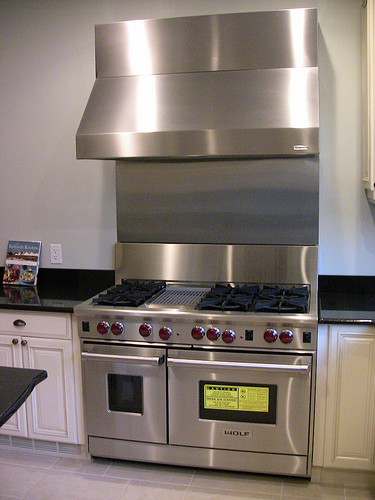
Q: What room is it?
A: It is a kitchen.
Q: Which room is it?
A: It is a kitchen.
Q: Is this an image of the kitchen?
A: Yes, it is showing the kitchen.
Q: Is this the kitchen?
A: Yes, it is the kitchen.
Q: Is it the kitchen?
A: Yes, it is the kitchen.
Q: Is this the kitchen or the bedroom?
A: It is the kitchen.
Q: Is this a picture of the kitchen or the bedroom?
A: It is showing the kitchen.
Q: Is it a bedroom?
A: No, it is a kitchen.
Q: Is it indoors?
A: Yes, it is indoors.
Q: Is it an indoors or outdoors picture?
A: It is indoors.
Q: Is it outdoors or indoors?
A: It is indoors.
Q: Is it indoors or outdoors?
A: It is indoors.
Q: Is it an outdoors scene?
A: No, it is indoors.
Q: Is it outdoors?
A: No, it is indoors.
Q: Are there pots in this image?
A: No, there are no pots.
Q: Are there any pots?
A: No, there are no pots.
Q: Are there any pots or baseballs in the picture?
A: No, there are no pots or baseballs.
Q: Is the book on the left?
A: Yes, the book is on the left of the image.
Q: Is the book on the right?
A: No, the book is on the left of the image.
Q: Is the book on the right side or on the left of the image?
A: The book is on the left of the image.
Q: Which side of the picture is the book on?
A: The book is on the left of the image.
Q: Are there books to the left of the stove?
A: Yes, there is a book to the left of the stove.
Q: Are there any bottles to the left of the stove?
A: No, there is a book to the left of the stove.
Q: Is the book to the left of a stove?
A: Yes, the book is to the left of a stove.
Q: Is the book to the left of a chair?
A: No, the book is to the left of a stove.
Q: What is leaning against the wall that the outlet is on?
A: The book is leaning against the wall.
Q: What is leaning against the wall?
A: The book is leaning against the wall.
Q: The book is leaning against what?
A: The book is leaning against the wall.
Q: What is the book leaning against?
A: The book is leaning against the wall.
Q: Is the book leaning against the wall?
A: Yes, the book is leaning against the wall.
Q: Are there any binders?
A: No, there are no binders.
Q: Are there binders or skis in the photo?
A: No, there are no binders or skis.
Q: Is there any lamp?
A: No, there are no lamps.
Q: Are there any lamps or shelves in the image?
A: No, there are no lamps or shelves.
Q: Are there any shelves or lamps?
A: No, there are no lamps or shelves.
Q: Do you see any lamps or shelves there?
A: No, there are no lamps or shelves.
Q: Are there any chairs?
A: No, there are no chairs.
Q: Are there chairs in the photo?
A: No, there are no chairs.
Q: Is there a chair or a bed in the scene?
A: No, there are no chairs or beds.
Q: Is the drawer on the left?
A: Yes, the drawer is on the left of the image.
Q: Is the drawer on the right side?
A: No, the drawer is on the left of the image.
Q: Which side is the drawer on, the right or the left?
A: The drawer is on the left of the image.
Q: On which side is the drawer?
A: The drawer is on the left of the image.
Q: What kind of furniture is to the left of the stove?
A: The piece of furniture is a drawer.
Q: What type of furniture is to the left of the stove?
A: The piece of furniture is a drawer.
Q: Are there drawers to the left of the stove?
A: Yes, there is a drawer to the left of the stove.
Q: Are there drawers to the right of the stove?
A: No, the drawer is to the left of the stove.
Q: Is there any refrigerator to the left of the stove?
A: No, there is a drawer to the left of the stove.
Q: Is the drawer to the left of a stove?
A: Yes, the drawer is to the left of a stove.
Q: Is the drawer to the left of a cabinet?
A: No, the drawer is to the left of a stove.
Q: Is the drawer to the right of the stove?
A: No, the drawer is to the left of the stove.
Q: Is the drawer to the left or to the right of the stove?
A: The drawer is to the left of the stove.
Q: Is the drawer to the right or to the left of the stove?
A: The drawer is to the left of the stove.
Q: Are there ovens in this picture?
A: Yes, there is an oven.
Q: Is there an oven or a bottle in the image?
A: Yes, there is an oven.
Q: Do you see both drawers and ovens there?
A: Yes, there are both an oven and a drawer.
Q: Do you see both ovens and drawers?
A: Yes, there are both an oven and a drawer.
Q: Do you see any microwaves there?
A: No, there are no microwaves.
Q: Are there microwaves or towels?
A: No, there are no microwaves or towels.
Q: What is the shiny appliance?
A: The appliance is an oven.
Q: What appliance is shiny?
A: The appliance is an oven.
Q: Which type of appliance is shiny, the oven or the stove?
A: The oven is shiny.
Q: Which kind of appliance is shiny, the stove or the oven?
A: The oven is shiny.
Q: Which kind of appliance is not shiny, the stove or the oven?
A: The stove is not shiny.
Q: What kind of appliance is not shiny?
A: The appliance is a stove.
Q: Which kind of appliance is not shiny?
A: The appliance is a stove.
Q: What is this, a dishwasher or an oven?
A: This is an oven.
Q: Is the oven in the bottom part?
A: Yes, the oven is in the bottom of the image.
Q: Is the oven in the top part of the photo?
A: No, the oven is in the bottom of the image.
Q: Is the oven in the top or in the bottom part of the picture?
A: The oven is in the bottom of the image.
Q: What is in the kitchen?
A: The oven is in the kitchen.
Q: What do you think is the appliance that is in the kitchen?
A: The appliance is an oven.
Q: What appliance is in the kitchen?
A: The appliance is an oven.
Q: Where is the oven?
A: The oven is in the kitchen.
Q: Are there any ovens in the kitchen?
A: Yes, there is an oven in the kitchen.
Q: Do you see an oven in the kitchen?
A: Yes, there is an oven in the kitchen.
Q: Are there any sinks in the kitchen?
A: No, there is an oven in the kitchen.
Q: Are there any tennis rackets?
A: No, there are no tennis rackets.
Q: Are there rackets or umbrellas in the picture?
A: No, there are no rackets or umbrellas.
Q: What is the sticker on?
A: The sticker is on the oven.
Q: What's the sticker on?
A: The sticker is on the oven.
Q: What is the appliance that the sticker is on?
A: The appliance is an oven.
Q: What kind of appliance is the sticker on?
A: The sticker is on the oven.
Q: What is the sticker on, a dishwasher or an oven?
A: The sticker is on an oven.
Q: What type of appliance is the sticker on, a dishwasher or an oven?
A: The sticker is on an oven.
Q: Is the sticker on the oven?
A: Yes, the sticker is on the oven.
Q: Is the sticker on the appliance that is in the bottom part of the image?
A: Yes, the sticker is on the oven.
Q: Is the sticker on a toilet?
A: No, the sticker is on the oven.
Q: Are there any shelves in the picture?
A: No, there are no shelves.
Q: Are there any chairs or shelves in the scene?
A: No, there are no shelves or chairs.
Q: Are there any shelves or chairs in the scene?
A: No, there are no shelves or chairs.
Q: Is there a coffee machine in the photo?
A: No, there are no coffee makers.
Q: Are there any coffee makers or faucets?
A: No, there are no coffee makers or faucets.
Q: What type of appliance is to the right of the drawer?
A: The appliance is a stove.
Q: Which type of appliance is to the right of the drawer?
A: The appliance is a stove.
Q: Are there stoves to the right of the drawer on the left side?
A: Yes, there is a stove to the right of the drawer.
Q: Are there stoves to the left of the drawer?
A: No, the stove is to the right of the drawer.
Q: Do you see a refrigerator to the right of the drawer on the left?
A: No, there is a stove to the right of the drawer.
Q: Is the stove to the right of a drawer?
A: Yes, the stove is to the right of a drawer.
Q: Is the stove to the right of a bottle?
A: No, the stove is to the right of a drawer.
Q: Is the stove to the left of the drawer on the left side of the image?
A: No, the stove is to the right of the drawer.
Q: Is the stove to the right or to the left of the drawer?
A: The stove is to the right of the drawer.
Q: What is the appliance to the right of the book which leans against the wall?
A: The appliance is a stove.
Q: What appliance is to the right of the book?
A: The appliance is a stove.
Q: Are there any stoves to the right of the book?
A: Yes, there is a stove to the right of the book.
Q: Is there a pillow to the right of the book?
A: No, there is a stove to the right of the book.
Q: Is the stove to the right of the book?
A: Yes, the stove is to the right of the book.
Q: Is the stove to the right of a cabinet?
A: No, the stove is to the right of the book.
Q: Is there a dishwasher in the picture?
A: No, there are no dishwashers.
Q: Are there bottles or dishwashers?
A: No, there are no dishwashers or bottles.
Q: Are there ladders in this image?
A: No, there are no ladders.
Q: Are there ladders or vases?
A: No, there are no ladders or vases.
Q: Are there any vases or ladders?
A: No, there are no ladders or vases.